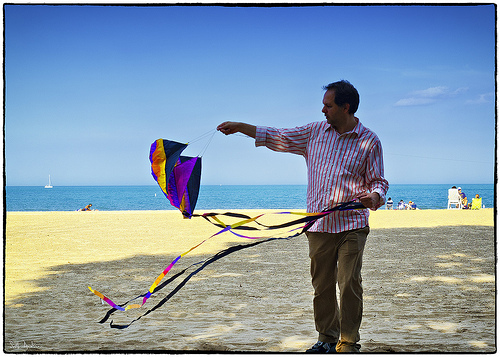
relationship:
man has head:
[260, 70, 389, 316] [318, 81, 368, 126]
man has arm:
[260, 70, 389, 316] [245, 116, 313, 158]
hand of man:
[213, 120, 242, 140] [260, 70, 389, 316]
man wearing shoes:
[260, 70, 389, 316] [303, 332, 369, 353]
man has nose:
[260, 70, 389, 316] [318, 108, 330, 114]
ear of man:
[346, 99, 353, 115] [260, 70, 389, 316]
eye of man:
[326, 101, 334, 108] [260, 70, 389, 316]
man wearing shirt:
[260, 70, 389, 316] [287, 132, 371, 222]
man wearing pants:
[260, 70, 389, 316] [301, 229, 364, 342]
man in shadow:
[260, 70, 389, 316] [366, 223, 489, 356]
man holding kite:
[260, 70, 389, 316] [143, 142, 232, 230]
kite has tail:
[143, 142, 232, 230] [201, 205, 302, 246]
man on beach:
[260, 70, 389, 316] [28, 186, 288, 325]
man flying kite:
[260, 70, 389, 316] [143, 142, 232, 230]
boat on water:
[34, 166, 63, 192] [35, 183, 153, 211]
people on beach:
[393, 194, 486, 224] [28, 186, 288, 325]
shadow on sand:
[366, 223, 489, 356] [79, 249, 487, 336]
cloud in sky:
[397, 87, 479, 115] [48, 18, 456, 96]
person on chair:
[452, 184, 468, 197] [442, 188, 458, 207]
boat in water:
[34, 166, 63, 192] [35, 183, 153, 211]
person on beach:
[452, 184, 468, 197] [28, 186, 288, 325]